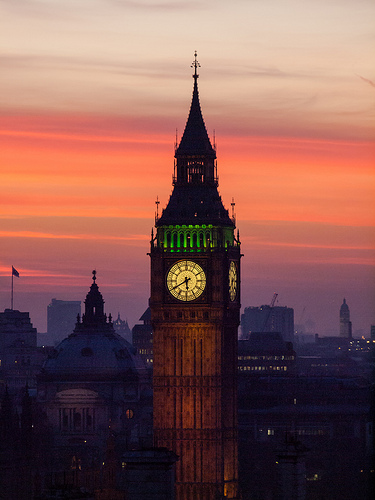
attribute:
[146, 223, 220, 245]
light — green